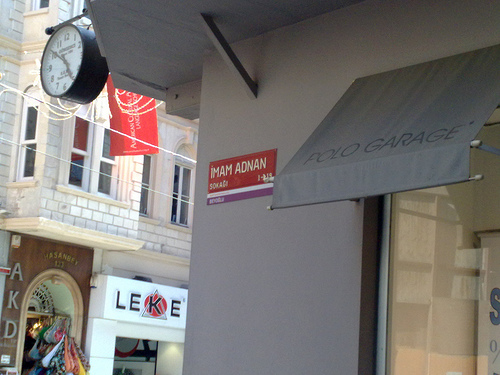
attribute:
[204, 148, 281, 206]
sign — red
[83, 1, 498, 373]
building — gray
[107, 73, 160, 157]
banner — red, hanging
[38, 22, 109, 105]
clock — black, hanging, round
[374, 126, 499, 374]
window — reflecting, reflective, glass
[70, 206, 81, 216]
brick — white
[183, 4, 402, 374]
wall — grey, gray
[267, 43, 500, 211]
awning — gray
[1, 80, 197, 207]
lines — white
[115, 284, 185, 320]
logo — painted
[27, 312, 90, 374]
purses — hanging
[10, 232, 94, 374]
window — brown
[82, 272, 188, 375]
entrance — white